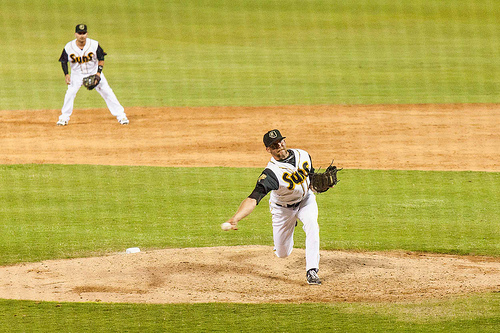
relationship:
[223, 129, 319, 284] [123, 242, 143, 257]
athlete throwing ball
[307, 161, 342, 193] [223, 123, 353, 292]
glove of player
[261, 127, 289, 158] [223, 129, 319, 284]
head of athlete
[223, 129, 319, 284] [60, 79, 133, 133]
athlete has legs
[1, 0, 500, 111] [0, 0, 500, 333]
green grass in baseball field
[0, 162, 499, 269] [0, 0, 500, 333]
green grass in baseball field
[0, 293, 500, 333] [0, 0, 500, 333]
green grass in baseball field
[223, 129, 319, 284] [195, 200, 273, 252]
athlete throws ball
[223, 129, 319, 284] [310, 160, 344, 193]
athlete holds glove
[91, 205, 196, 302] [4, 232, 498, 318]
box on mound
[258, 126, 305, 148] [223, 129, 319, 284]
hat on athlete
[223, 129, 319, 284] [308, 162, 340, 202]
athlete wearing glove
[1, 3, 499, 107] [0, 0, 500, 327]
green grass on baseball field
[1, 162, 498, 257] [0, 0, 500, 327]
green grass on baseball field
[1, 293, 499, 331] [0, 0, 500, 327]
green grass on baseball field